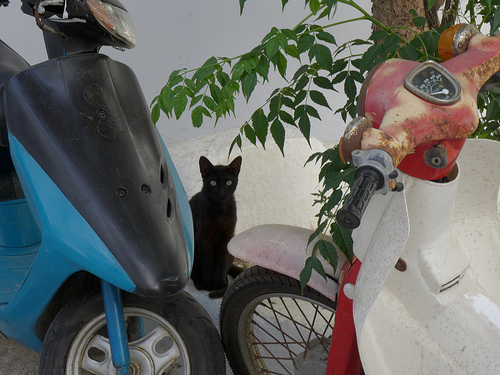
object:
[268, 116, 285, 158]
green foliage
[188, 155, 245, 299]
cat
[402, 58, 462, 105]
gauge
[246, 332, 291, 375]
spokes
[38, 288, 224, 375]
tire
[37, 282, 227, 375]
front wheels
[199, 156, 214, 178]
ear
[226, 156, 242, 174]
ear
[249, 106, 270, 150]
leaves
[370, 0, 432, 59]
trunk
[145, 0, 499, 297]
plant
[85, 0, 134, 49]
light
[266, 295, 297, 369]
spoke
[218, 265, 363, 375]
wheel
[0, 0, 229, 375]
moped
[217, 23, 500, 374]
moped